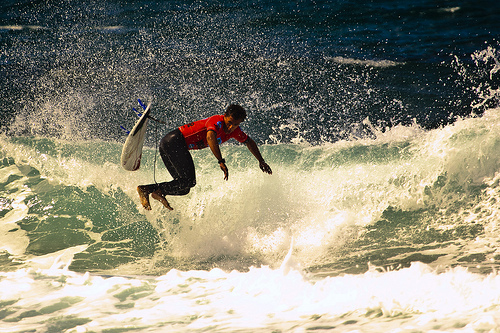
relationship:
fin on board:
[123, 93, 165, 132] [100, 78, 168, 183]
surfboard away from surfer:
[115, 94, 163, 175] [109, 77, 278, 217]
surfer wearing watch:
[109, 77, 278, 217] [210, 154, 227, 168]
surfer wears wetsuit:
[109, 77, 278, 217] [143, 129, 202, 199]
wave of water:
[8, 126, 498, 261] [0, 3, 499, 329]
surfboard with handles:
[115, 94, 163, 175] [131, 95, 142, 124]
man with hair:
[135, 101, 272, 214] [222, 103, 248, 122]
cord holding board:
[144, 111, 159, 187] [121, 94, 155, 171]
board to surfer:
[121, 94, 155, 171] [109, 77, 278, 217]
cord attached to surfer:
[144, 111, 159, 187] [109, 77, 278, 217]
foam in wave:
[253, 99, 453, 275] [16, 111, 454, 293]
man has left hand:
[135, 101, 272, 214] [256, 159, 274, 176]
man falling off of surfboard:
[135, 101, 272, 214] [118, 91, 153, 170]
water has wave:
[0, 3, 499, 329] [8, 126, 498, 261]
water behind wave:
[0, 3, 499, 329] [2, 131, 499, 276]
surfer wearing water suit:
[109, 77, 278, 217] [138, 113, 248, 197]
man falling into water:
[135, 101, 272, 214] [0, 3, 499, 329]